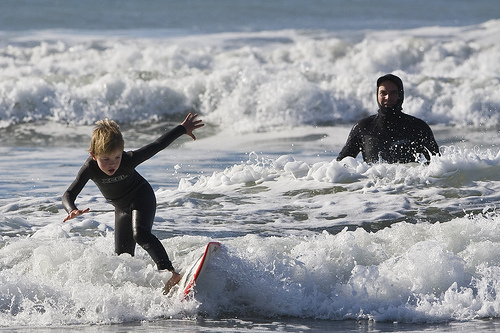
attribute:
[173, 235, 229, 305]
surfboard — white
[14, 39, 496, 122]
wave — foamy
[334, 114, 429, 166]
wetsuit — black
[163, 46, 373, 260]
water — white  , foamy 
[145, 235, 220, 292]
surfboard — tilted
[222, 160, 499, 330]
water — white, foamy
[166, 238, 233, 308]
surfboard — red, white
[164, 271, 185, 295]
foot — small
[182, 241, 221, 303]
edge — red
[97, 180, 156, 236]
wetsuit — black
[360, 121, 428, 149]
wetsuit — black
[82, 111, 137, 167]
hair — blonde